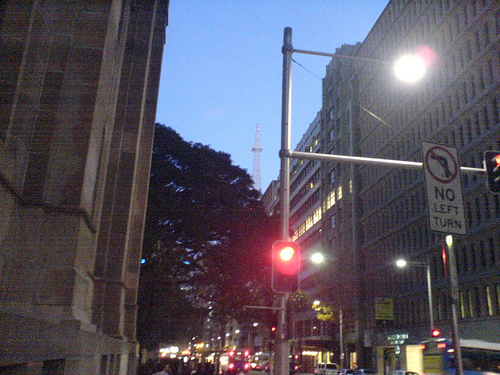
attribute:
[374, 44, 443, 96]
light — on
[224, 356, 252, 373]
car — pictured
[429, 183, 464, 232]
words — black, No Left Turn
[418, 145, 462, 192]
circle — red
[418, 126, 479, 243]
arrow — black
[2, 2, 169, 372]
building — large , stone, tall, brown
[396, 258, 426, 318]
light — street, illuminated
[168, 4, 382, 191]
sky — clear, blue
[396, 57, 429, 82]
light — glowing, red, traffic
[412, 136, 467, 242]
sign — red, black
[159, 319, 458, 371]
lights — plentiful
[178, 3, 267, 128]
sky — blue, clear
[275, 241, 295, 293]
light — red, traffic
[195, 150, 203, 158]
leaves — green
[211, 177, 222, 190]
leaves — green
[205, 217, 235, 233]
leaves — green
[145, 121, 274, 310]
tree — in bloom, large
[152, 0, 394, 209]
sky — clear, blue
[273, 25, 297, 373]
post — tall , metal 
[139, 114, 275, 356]
tree — tall, green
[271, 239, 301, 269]
light — red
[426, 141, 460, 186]
circle — red